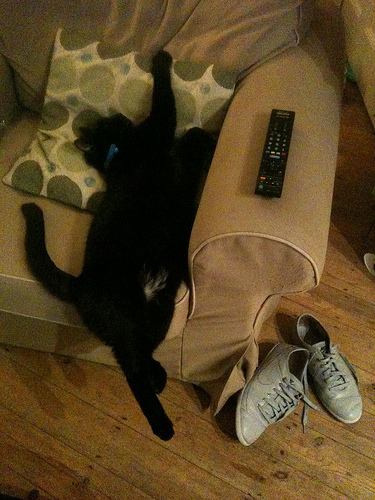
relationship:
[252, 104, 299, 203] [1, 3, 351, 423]
remote on couch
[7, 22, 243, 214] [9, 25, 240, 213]
pillow has dots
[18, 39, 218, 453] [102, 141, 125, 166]
cat wearing collar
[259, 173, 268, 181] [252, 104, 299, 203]
button on remote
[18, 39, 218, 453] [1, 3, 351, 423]
cat on couch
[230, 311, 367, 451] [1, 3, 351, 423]
sneakers are on side of couch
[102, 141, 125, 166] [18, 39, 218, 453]
collar on cat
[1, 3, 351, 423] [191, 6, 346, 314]
couch has arm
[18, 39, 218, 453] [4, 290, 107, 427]
cat has shadow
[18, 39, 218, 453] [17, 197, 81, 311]
cat has tail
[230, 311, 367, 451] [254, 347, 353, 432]
sneakers have shoelaces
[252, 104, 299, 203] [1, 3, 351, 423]
remote on sofa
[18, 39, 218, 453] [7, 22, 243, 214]
cat on pillow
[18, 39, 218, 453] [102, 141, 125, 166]
cat has collar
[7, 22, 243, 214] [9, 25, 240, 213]
pillow has circles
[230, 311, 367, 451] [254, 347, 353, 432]
shoes have strings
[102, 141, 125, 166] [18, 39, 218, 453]
collar for cat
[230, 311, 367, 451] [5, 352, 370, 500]
shoes are on floor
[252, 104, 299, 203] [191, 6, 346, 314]
remote on arm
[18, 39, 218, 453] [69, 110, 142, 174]
cat has head